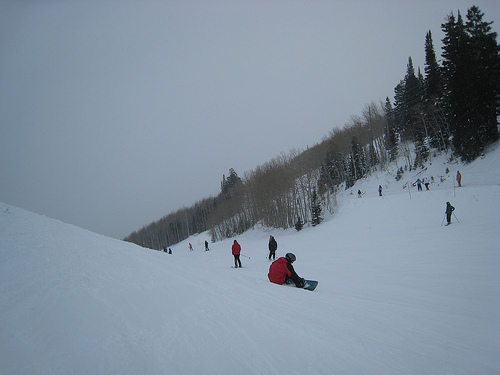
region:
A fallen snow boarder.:
[266, 251, 322, 295]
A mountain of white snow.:
[1, 178, 150, 335]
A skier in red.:
[225, 235, 250, 272]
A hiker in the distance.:
[265, 230, 276, 259]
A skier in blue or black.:
[435, 198, 462, 230]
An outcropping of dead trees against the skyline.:
[123, 178, 228, 250]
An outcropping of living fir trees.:
[416, 7, 499, 162]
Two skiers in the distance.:
[348, 181, 386, 199]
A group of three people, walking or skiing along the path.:
[391, 160, 473, 197]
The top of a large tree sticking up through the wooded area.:
[214, 161, 241, 198]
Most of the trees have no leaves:
[121, 4, 498, 253]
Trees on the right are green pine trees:
[308, 3, 496, 225]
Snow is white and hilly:
[1, 138, 498, 373]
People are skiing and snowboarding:
[161, 171, 464, 294]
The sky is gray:
[2, 0, 498, 240]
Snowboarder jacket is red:
[266, 254, 318, 292]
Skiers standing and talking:
[228, 234, 283, 266]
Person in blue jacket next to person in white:
[412, 174, 432, 194]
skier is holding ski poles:
[441, 200, 463, 231]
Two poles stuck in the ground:
[400, 177, 464, 202]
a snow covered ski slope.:
[0, 203, 497, 370]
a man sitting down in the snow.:
[260, 233, 334, 305]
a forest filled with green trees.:
[378, 3, 498, 168]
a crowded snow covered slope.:
[161, 124, 473, 311]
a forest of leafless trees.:
[119, 98, 386, 270]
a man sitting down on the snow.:
[248, 246, 333, 291]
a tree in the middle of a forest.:
[213, 163, 254, 213]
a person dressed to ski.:
[428, 205, 463, 249]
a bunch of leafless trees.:
[268, 156, 336, 248]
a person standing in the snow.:
[225, 231, 252, 267]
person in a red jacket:
[265, 247, 320, 293]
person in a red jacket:
[227, 237, 245, 269]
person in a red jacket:
[454, 170, 464, 185]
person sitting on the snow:
[261, 243, 324, 290]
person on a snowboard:
[264, 247, 322, 293]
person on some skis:
[264, 233, 279, 260]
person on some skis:
[227, 237, 244, 270]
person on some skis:
[438, 199, 456, 224]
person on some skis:
[375, 183, 384, 196]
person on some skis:
[200, 236, 212, 254]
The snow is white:
[31, 241, 166, 344]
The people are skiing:
[120, 230, 224, 277]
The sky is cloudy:
[57, 117, 243, 241]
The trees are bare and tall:
[149, 150, 294, 238]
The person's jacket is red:
[265, 253, 298, 284]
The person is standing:
[420, 174, 498, 304]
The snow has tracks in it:
[199, 290, 386, 363]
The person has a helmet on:
[269, 243, 313, 271]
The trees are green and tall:
[394, 4, 487, 132]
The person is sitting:
[255, 251, 357, 329]